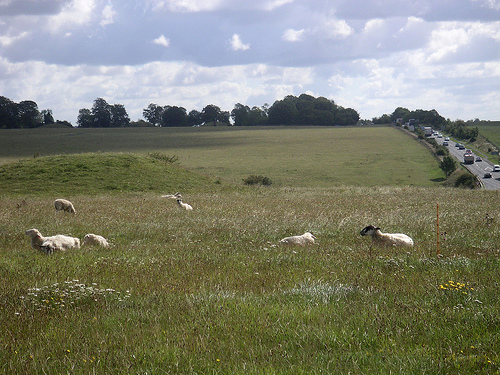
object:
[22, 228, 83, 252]
sheep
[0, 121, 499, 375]
grass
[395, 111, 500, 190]
highway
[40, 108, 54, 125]
trees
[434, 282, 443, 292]
flowers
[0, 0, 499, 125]
sky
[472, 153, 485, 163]
truck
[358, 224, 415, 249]
sheep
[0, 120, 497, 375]
field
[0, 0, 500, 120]
clouds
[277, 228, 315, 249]
sheep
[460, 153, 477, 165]
cars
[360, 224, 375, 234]
head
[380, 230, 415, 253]
body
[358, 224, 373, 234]
face